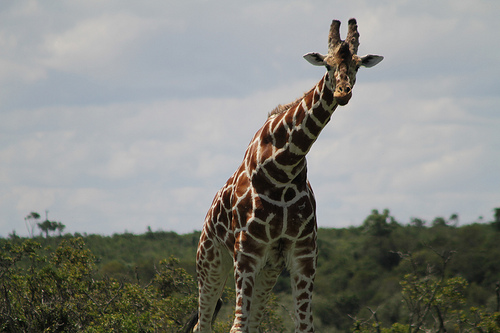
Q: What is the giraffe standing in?
A: Brush and bushes.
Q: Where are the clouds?
A: In the sky.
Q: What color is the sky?
A: Light blue.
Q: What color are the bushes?
A: Green.